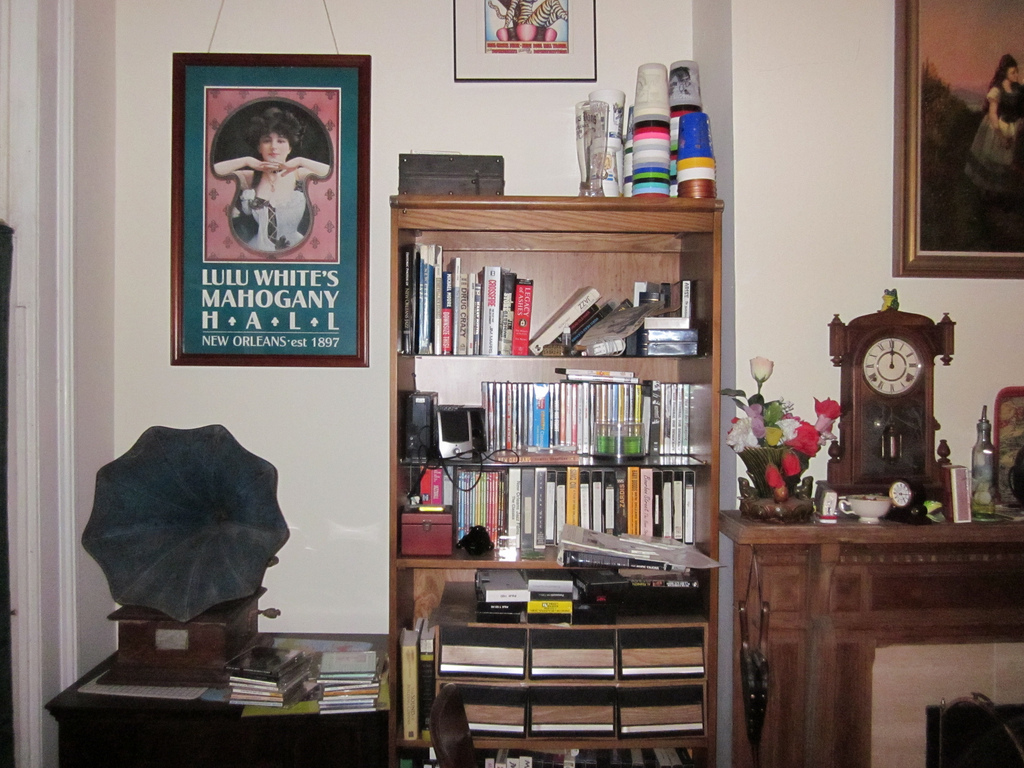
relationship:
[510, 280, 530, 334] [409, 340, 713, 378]
book on shelf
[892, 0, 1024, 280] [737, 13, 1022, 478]
antique art on wall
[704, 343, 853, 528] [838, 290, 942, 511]
floral sitting beside clock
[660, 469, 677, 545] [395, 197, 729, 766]
book on shelf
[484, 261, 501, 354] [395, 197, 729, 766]
book on shelf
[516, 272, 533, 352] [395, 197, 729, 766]
book on shelf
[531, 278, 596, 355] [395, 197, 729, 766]
book on shelf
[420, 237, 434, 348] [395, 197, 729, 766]
book on shelf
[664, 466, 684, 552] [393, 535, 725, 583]
book on a shelf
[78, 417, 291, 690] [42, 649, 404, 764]
phonograph sitting on shelf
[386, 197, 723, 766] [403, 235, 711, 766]
wooden bookcase full miscellaneous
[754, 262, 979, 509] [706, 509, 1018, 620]
clock sitting on mantle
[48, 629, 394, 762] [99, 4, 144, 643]
end table in corner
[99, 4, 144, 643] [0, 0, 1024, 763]
corner of room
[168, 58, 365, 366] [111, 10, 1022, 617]
antique art on wall